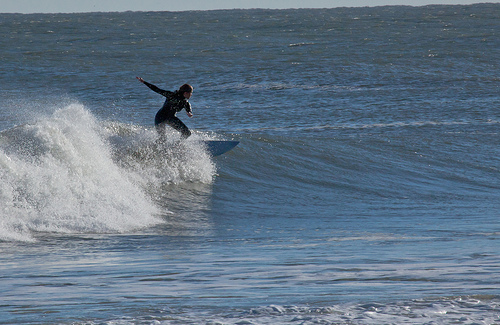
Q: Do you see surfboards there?
A: Yes, there is a surfboard.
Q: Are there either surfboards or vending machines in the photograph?
A: Yes, there is a surfboard.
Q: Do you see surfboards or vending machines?
A: Yes, there is a surfboard.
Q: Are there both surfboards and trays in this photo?
A: No, there is a surfboard but no trays.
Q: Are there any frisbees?
A: No, there are no frisbees.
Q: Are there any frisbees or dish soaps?
A: No, there are no frisbees or dish soaps.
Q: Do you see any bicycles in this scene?
A: No, there are no bicycles.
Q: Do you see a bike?
A: No, there are no bikes.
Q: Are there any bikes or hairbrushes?
A: No, there are no bikes or hairbrushes.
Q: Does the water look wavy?
A: Yes, the water is wavy.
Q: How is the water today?
A: The water is wavy.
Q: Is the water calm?
A: No, the water is wavy.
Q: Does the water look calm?
A: No, the water is wavy.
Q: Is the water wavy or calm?
A: The water is wavy.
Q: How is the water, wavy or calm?
A: The water is wavy.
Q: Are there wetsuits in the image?
A: Yes, there is a wetsuit.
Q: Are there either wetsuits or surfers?
A: Yes, there is a wetsuit.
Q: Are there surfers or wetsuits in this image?
A: Yes, there is a wetsuit.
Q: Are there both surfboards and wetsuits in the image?
A: Yes, there are both a wetsuit and a surfboard.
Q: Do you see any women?
A: Yes, there is a woman.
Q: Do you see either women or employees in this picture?
A: Yes, there is a woman.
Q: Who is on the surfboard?
A: The woman is on the surfboard.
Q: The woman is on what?
A: The woman is on the surfboard.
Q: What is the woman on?
A: The woman is on the surfboard.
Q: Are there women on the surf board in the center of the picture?
A: Yes, there is a woman on the surfboard.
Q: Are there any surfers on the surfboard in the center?
A: No, there is a woman on the surf board.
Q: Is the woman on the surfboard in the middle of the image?
A: Yes, the woman is on the surfboard.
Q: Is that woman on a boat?
A: No, the woman is on the surfboard.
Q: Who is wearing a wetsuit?
A: The woman is wearing a wetsuit.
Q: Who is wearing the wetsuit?
A: The woman is wearing a wetsuit.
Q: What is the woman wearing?
A: The woman is wearing a wet suit.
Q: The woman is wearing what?
A: The woman is wearing a wet suit.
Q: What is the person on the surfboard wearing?
A: The woman is wearing a wet suit.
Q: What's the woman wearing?
A: The woman is wearing a wet suit.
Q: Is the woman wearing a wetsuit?
A: Yes, the woman is wearing a wetsuit.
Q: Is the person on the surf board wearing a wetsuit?
A: Yes, the woman is wearing a wetsuit.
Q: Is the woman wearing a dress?
A: No, the woman is wearing a wetsuit.